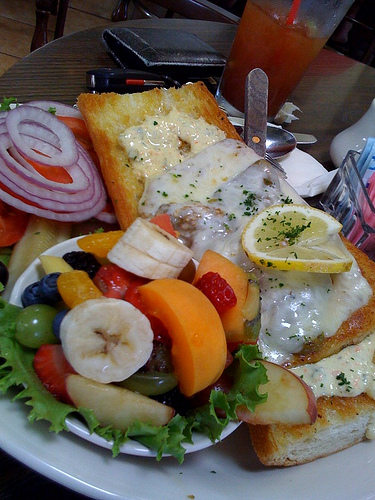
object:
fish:
[76, 81, 374, 472]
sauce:
[110, 278, 127, 299]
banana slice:
[60, 296, 152, 386]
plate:
[0, 92, 374, 497]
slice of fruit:
[60, 370, 178, 440]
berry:
[194, 271, 237, 313]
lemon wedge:
[238, 199, 352, 274]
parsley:
[273, 218, 313, 242]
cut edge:
[258, 403, 373, 465]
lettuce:
[0, 299, 101, 433]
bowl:
[8, 232, 261, 457]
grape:
[13, 302, 57, 347]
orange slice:
[53, 269, 104, 309]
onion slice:
[5, 104, 77, 168]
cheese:
[136, 137, 372, 366]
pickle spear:
[7, 210, 76, 296]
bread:
[79, 83, 245, 231]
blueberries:
[36, 270, 66, 298]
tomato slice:
[0, 156, 73, 243]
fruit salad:
[13, 210, 261, 465]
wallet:
[102, 14, 226, 91]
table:
[4, 11, 373, 161]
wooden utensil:
[242, 65, 266, 158]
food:
[63, 372, 174, 431]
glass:
[215, 0, 357, 125]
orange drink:
[217, 0, 326, 121]